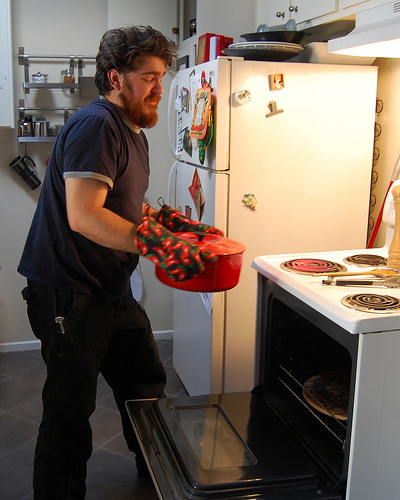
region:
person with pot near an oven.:
[38, 8, 358, 418]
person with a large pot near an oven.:
[48, 20, 372, 468]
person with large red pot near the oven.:
[44, 32, 360, 468]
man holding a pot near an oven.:
[48, 20, 376, 460]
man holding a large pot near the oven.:
[32, 20, 368, 476]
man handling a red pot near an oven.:
[32, 17, 372, 481]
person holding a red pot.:
[88, 164, 248, 308]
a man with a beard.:
[72, 20, 172, 136]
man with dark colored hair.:
[88, 20, 180, 144]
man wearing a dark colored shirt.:
[36, 29, 178, 314]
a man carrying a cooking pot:
[15, 28, 249, 498]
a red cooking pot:
[155, 230, 247, 290]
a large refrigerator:
[166, 65, 383, 409]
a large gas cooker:
[256, 241, 388, 481]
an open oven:
[262, 315, 347, 477]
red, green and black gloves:
[138, 203, 215, 278]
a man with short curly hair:
[97, 24, 181, 121]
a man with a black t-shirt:
[13, 29, 178, 298]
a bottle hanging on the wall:
[10, 153, 40, 192]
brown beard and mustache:
[123, 92, 176, 137]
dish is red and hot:
[143, 210, 248, 294]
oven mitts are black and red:
[131, 183, 228, 288]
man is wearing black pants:
[23, 261, 169, 481]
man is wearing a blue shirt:
[8, 125, 190, 297]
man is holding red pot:
[130, 195, 246, 297]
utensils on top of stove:
[318, 264, 395, 298]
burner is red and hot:
[280, 245, 341, 288]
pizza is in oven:
[300, 361, 356, 430]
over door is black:
[116, 368, 312, 499]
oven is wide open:
[243, 283, 362, 481]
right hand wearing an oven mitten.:
[134, 224, 210, 284]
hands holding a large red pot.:
[139, 195, 254, 312]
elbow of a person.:
[60, 188, 113, 258]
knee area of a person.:
[105, 358, 179, 420]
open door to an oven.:
[109, 390, 329, 488]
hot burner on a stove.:
[274, 251, 348, 279]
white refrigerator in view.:
[169, 52, 362, 200]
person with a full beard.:
[88, 12, 168, 132]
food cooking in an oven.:
[276, 340, 344, 452]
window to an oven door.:
[172, 397, 249, 469]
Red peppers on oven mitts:
[100, 149, 302, 330]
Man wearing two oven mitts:
[120, 211, 289, 367]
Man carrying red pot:
[167, 222, 258, 329]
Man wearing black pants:
[31, 309, 101, 441]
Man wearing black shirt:
[17, 223, 94, 296]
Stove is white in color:
[274, 228, 359, 408]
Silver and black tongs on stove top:
[326, 260, 395, 308]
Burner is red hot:
[283, 229, 333, 311]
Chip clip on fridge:
[258, 88, 316, 148]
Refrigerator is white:
[166, 53, 375, 186]